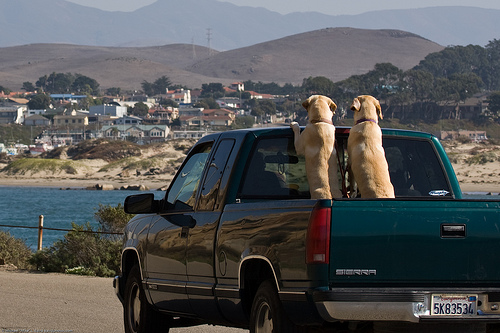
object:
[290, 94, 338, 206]
dogs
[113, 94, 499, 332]
truck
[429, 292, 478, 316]
tag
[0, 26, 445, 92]
mountains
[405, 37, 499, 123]
trees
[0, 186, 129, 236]
water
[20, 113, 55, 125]
houses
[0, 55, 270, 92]
hill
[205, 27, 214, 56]
poles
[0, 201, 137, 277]
bushes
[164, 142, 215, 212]
window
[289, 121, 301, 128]
paws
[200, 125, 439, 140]
roof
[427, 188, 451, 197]
sticker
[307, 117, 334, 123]
collars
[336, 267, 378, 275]
name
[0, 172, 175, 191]
shoreline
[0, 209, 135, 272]
fence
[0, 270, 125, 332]
road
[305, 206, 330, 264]
tail light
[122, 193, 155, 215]
mirror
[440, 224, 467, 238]
latch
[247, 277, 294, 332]
tire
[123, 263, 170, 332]
tire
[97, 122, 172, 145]
house